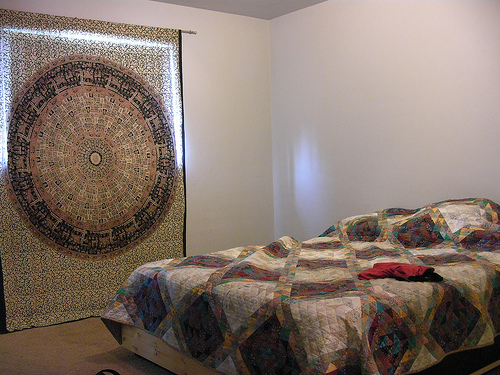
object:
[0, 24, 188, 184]
window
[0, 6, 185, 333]
curtain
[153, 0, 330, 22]
ceiling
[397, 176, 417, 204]
ground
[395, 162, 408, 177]
ground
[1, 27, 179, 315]
shade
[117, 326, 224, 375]
bed frame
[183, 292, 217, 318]
triangles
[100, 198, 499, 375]
bed cover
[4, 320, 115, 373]
floor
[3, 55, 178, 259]
circle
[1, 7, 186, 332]
drape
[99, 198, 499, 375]
patterned cover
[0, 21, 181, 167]
sun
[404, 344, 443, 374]
triangles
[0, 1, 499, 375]
room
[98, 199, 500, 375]
bed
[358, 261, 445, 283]
cloth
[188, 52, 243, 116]
walls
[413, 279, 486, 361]
square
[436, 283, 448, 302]
triangle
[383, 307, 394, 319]
triangle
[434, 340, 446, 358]
triangle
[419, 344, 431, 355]
triangle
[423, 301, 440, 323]
triangle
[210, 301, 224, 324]
triangle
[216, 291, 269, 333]
triangle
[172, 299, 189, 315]
triangle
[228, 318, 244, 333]
triangle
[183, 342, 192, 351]
triangle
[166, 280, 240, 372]
square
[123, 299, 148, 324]
triangle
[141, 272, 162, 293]
triangle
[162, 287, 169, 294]
triangle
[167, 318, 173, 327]
triangle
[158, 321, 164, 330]
triangle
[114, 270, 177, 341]
square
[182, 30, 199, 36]
rod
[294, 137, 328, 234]
light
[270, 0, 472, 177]
wall